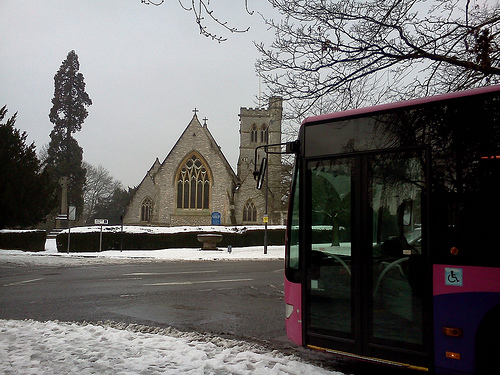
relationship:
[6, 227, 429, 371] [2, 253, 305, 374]
snow on road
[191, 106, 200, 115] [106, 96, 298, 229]
cross on church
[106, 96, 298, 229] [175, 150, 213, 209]
church has window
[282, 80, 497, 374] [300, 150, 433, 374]
bus has doors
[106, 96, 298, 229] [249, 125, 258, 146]
church has window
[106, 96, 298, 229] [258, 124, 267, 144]
church has window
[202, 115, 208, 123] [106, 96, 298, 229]
cross on church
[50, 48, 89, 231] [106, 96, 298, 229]
tree near church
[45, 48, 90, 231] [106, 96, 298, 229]
tree next to church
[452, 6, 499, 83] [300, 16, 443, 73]
trees with branches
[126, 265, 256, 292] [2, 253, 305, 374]
markings on road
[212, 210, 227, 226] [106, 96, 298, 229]
sign standing in front of church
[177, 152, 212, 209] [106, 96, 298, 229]
window on church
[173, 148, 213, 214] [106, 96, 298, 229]
arched window in front of church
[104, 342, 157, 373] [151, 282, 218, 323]
snow by road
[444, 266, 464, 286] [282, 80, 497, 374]
symbol on bus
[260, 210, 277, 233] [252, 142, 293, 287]
sign on pole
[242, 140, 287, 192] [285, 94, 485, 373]
mirror attached to bus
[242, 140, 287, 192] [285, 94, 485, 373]
mirror mounted on bus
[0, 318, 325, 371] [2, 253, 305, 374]
snow covering road